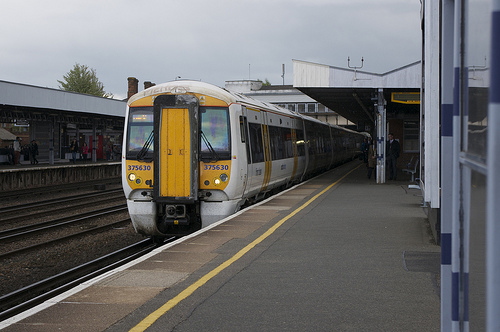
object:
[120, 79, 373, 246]
passenger train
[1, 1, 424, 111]
sky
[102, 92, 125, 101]
cloud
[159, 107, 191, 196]
train door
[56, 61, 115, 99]
tree top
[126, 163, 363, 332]
line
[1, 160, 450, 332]
walkway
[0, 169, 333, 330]
line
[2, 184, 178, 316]
track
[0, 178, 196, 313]
ground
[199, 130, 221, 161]
wiper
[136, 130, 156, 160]
wiper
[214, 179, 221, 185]
light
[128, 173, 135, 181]
light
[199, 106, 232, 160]
window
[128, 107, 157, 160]
window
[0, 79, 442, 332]
railway station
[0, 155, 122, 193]
platform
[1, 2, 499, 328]
photo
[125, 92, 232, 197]
front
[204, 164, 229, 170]
numbers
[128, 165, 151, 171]
numbers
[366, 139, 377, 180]
woman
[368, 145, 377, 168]
coat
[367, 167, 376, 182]
pants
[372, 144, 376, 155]
shirt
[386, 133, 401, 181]
man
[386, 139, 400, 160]
jacket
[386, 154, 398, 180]
pants